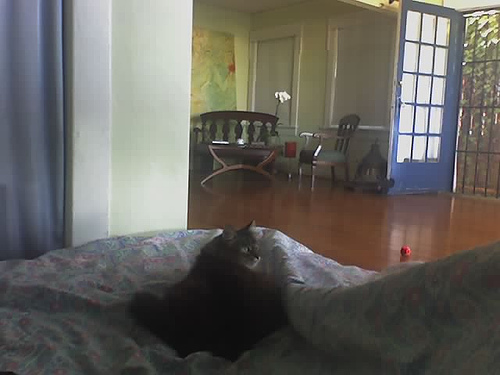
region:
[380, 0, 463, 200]
THE DOOR IS BLUE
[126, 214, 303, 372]
THE CAT IS ON THE BED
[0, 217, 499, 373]
THE BLANKET IS GREY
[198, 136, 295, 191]
THE TABLE IS BROWN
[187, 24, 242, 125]
THE PAINTING IS ON THE WALL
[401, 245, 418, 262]
THE BALL IS ON THE FLOOR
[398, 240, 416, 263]
THE BALL IS RED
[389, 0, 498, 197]
THE DOOR IS OPEN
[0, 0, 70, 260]
THE CURTAIN IS BLUE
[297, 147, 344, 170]
THE CHAIR CUSHION IS GREEN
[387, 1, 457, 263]
door is blue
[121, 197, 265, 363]
cat lying the sheet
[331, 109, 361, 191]
wooden chair by the door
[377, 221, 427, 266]
red ball on the floor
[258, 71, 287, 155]
white flowers in a vase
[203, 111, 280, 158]
wooden bench behind the table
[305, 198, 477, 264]
dark wooden floors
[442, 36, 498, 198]
metal door has bars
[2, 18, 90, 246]
curtain is light blue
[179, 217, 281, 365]
cat has brown and black hair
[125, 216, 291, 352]
the cat on the bed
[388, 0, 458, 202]
the door is open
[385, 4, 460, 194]
the door is blue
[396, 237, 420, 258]
the ball on the floor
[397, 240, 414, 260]
the ball is red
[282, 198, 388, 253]
the floor is wooden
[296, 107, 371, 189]
the chair near the wall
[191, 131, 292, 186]
the coffee table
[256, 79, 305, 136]
the flower near the wall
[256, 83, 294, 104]
the white flower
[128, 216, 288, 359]
Cat looking to the right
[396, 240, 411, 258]
Red ball on the floor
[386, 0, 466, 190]
The blue door is open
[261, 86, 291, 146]
White flower in a pot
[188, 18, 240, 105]
Abstract painting with a red dot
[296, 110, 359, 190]
Chair with arms and a padded seat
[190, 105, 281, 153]
wooden bench with a high back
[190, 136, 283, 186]
coffee table with a book and coffee cup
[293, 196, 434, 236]
wooden floor that is shiny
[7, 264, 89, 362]
paisley blanket with wrinkles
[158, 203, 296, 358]
grey cat laying down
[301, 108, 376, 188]
chair with green seat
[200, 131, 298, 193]
coffee table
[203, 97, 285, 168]
bench behind the coffee table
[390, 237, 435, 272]
red ball on the ground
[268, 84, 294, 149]
white flowers on the table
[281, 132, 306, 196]
red lamp in the background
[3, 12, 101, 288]
blue curtains on the left side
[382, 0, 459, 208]
blue door on the right side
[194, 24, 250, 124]
large picture on the wall